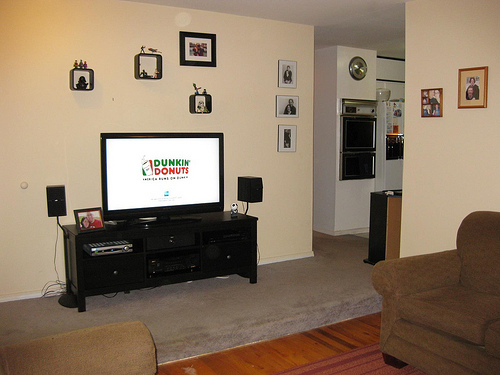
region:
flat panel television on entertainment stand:
[97, 127, 224, 224]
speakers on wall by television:
[39, 173, 264, 218]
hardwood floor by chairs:
[149, 310, 388, 374]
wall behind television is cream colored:
[0, 0, 313, 297]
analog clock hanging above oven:
[347, 53, 369, 83]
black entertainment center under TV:
[56, 208, 263, 316]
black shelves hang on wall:
[69, 43, 211, 113]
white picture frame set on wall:
[275, 57, 300, 153]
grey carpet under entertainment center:
[0, 230, 383, 364]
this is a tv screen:
[84, 108, 262, 229]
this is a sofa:
[377, 238, 492, 373]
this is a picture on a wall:
[67, 55, 107, 93]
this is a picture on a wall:
[175, 28, 220, 71]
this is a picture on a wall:
[279, 122, 298, 153]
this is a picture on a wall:
[270, 94, 298, 119]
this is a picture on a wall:
[271, 54, 303, 89]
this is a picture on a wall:
[458, 60, 497, 114]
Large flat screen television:
[95, 129, 226, 216]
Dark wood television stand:
[58, 208, 259, 315]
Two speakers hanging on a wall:
[43, 173, 265, 218]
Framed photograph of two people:
[68, 206, 108, 231]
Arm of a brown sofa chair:
[2, 316, 159, 371]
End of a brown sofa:
[369, 208, 499, 371]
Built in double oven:
[337, 96, 378, 182]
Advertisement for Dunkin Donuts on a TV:
[139, 155, 192, 184]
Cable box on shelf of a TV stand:
[85, 239, 135, 254]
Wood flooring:
[154, 309, 449, 373]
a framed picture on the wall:
[179, 31, 215, 64]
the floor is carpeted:
[2, 226, 382, 366]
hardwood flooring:
[160, 311, 391, 373]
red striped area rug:
[285, 348, 412, 374]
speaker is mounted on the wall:
[47, 185, 66, 216]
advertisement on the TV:
[141, 156, 191, 183]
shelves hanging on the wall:
[67, 46, 212, 113]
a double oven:
[340, 98, 377, 180]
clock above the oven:
[350, 56, 367, 80]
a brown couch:
[372, 212, 499, 373]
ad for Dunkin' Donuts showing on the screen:
[99, 130, 226, 217]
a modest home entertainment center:
[39, 125, 271, 315]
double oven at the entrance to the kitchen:
[336, 92, 380, 187]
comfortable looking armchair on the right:
[366, 206, 498, 371]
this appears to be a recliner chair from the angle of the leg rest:
[368, 204, 499, 371]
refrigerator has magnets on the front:
[374, 95, 404, 192]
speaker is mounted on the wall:
[43, 182, 70, 222]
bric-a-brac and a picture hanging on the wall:
[65, 26, 220, 118]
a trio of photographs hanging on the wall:
[272, 53, 304, 157]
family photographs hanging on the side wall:
[417, 63, 492, 122]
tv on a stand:
[23, 119, 273, 286]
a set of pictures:
[259, 45, 311, 164]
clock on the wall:
[345, 54, 368, 82]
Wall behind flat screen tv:
[0, 0, 316, 303]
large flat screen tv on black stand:
[59, 129, 261, 313]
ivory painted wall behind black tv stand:
[1, 2, 315, 303]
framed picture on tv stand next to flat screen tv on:
[59, 131, 262, 314]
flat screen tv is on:
[99, 130, 225, 225]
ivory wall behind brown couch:
[368, 0, 498, 374]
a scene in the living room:
[18, 49, 475, 374]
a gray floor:
[4, 240, 387, 357]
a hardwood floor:
[153, 296, 388, 371]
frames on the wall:
[52, 31, 303, 177]